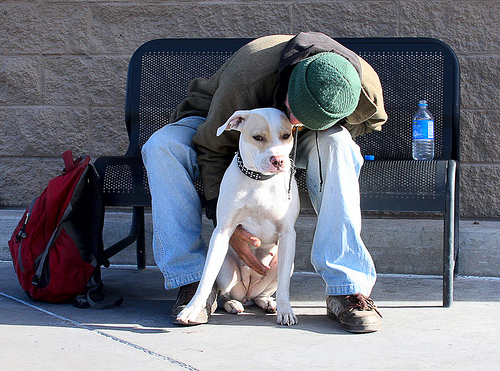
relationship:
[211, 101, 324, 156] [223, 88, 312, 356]
ears are on dog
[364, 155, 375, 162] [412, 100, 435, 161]
blue cap to bottle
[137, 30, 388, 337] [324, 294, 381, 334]
man wearing shoe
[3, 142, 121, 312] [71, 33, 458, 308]
backpack against a bench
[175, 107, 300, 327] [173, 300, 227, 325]
dog has paw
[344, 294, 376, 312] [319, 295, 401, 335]
brown laces of shoe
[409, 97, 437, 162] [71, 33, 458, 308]
bottle on bench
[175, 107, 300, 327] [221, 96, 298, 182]
dog has head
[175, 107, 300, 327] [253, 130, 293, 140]
dog has eye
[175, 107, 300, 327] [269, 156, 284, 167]
dog has nose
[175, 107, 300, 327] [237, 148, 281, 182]
dog has black collar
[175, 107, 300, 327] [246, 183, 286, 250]
dog has chest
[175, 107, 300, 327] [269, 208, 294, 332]
dog has paw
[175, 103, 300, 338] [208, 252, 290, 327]
dog has hind legs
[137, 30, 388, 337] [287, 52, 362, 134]
man wears hat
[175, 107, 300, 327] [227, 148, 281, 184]
dog wearing black collar